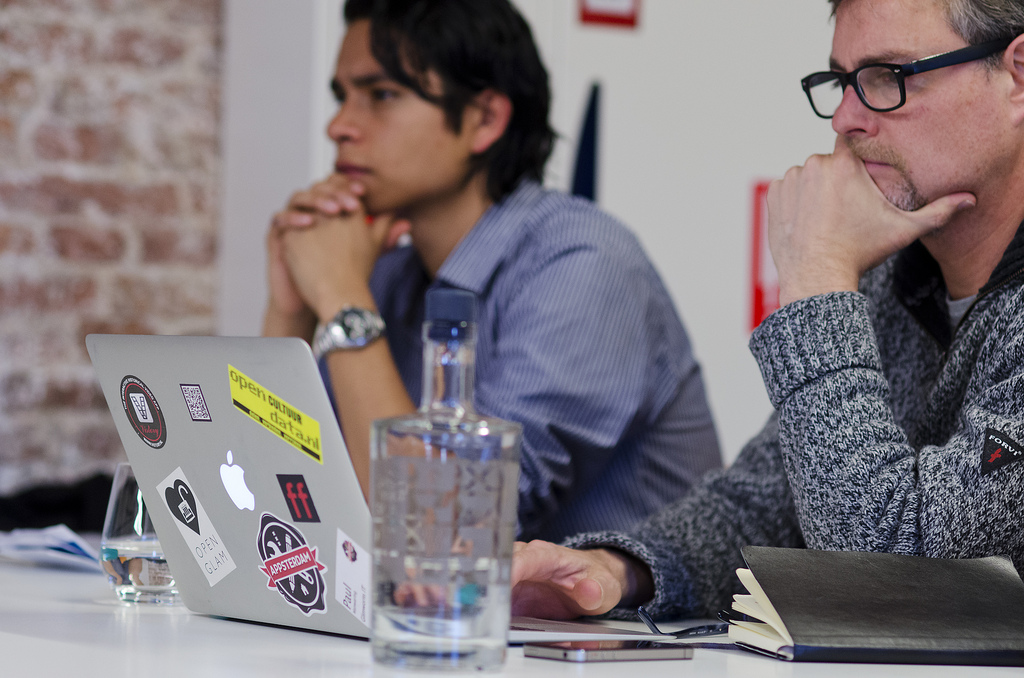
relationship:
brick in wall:
[53, 219, 129, 254] [0, 3, 225, 494]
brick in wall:
[132, 218, 213, 264] [0, 3, 225, 494]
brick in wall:
[112, 262, 218, 313] [0, 3, 225, 494]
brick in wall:
[2, 271, 105, 314] [0, 3, 225, 494]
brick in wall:
[3, 361, 106, 410] [0, 3, 225, 494]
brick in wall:
[2, 411, 61, 482] [0, 3, 225, 494]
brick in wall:
[39, 19, 177, 71] [0, 3, 225, 494]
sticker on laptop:
[230, 373, 322, 451] [85, 332, 675, 642]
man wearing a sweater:
[460, 5, 1022, 619] [562, 232, 1021, 628]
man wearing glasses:
[460, 5, 1022, 619] [802, 31, 1019, 120]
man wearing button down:
[240, 7, 727, 550] [319, 179, 727, 538]